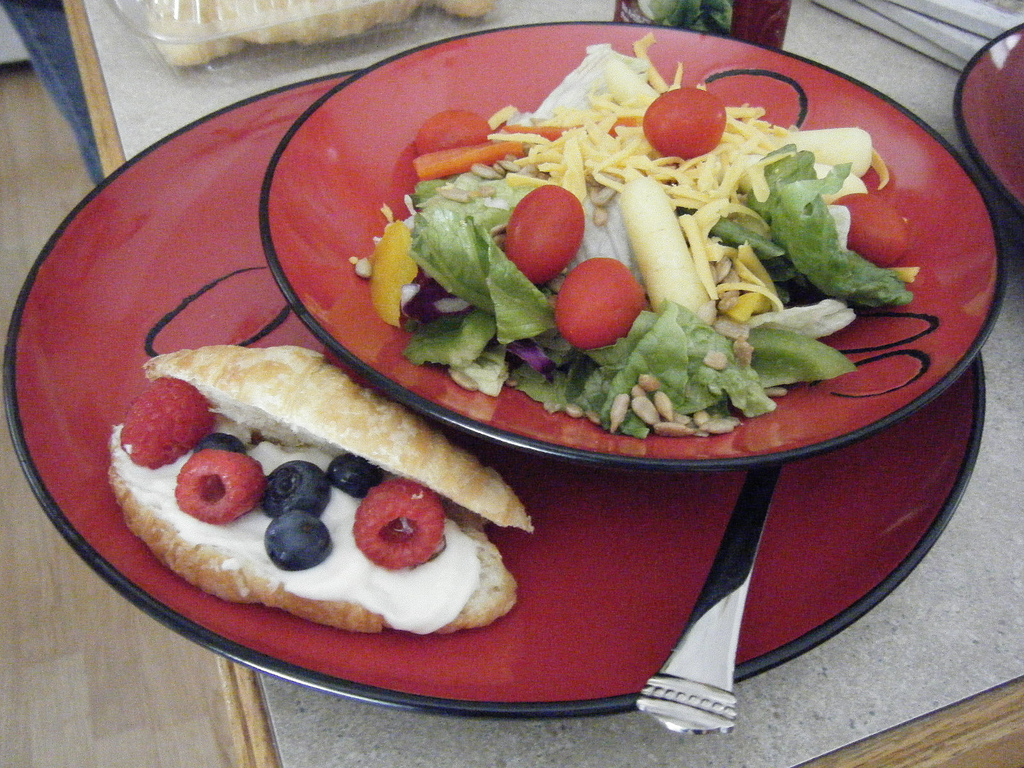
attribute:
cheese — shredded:
[606, 117, 781, 238]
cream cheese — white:
[123, 402, 502, 647]